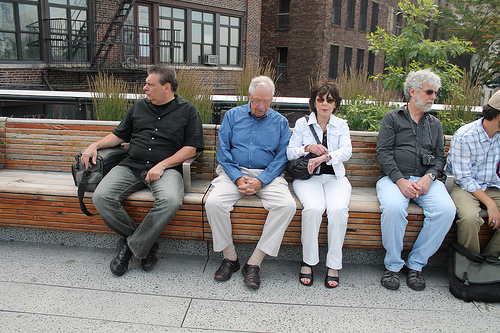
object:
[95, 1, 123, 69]
brick wall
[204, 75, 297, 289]
man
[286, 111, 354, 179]
blouse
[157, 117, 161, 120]
buttons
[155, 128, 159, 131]
buttons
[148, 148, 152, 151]
buttons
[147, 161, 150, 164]
buttons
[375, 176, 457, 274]
jeans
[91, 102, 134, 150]
arm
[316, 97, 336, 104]
sunglasses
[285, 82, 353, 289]
woman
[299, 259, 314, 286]
sandal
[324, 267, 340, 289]
sandal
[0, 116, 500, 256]
bench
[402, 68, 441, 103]
hair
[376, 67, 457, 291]
man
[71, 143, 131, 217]
duffel bag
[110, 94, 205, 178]
shirt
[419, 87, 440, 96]
glasses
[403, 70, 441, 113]
man's head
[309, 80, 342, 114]
brown hair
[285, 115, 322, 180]
purse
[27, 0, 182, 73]
starway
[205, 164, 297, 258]
pants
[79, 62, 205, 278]
man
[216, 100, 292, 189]
shirt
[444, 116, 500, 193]
shirt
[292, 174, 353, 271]
pants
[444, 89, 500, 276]
man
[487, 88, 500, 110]
cap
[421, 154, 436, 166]
camera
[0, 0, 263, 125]
building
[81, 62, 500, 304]
five people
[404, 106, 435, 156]
strap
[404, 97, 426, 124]
neck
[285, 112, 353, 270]
white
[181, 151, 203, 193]
arm rest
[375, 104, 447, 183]
shirt